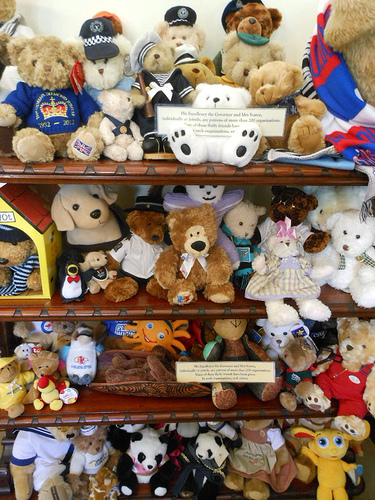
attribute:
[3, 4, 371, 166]
stuffed animals — bunched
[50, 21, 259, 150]
animals — shelf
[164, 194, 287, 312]
teddy bear — brown, holding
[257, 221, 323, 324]
rabbit — plush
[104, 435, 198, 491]
panda — small, stuffed, plush, fluffy, white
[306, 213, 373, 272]
bear — fluffy, white, teddy, brown, here, holding, wearing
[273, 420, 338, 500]
plush — yelow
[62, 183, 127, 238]
dog — plush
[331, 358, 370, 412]
overalls — red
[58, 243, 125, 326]
penguin — stuffed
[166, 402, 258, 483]
bear — panda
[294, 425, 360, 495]
bunny — stuffed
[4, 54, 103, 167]
toy — wearing, stuffed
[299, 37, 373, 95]
scarf — blue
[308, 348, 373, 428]
coveralls — red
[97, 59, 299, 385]
toys — several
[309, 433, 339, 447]
eyes — large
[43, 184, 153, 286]
doggie — beige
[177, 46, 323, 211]
polar bear — white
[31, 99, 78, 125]
shirt — royal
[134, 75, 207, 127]
dress — black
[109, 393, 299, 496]
pandas — displayed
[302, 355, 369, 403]
jumpsuit — red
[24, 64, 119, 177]
outfit — sporty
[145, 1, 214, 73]
bear — officer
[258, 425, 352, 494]
stuffed toy — yellow